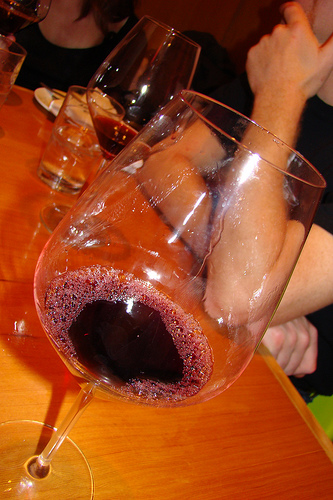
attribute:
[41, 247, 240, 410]
wine — red, purple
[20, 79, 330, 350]
glass — clear, large, small, short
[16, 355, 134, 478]
stem — thin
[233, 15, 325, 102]
hand — red, here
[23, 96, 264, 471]
table — brown, here, wooden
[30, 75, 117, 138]
plate — white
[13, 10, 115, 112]
top — black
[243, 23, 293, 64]
knuckle — red, here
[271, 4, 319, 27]
finger — red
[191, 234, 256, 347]
elbow — here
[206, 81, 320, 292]
shirt — black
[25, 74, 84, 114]
knife — metal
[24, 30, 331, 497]
glasses — here